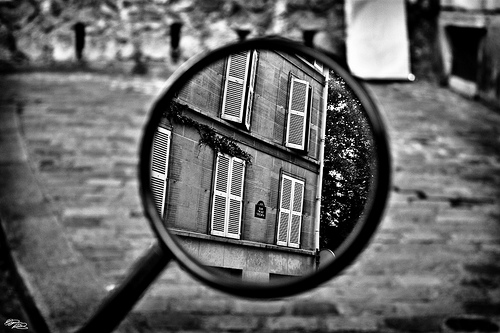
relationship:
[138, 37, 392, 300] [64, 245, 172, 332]
rear view mirror has arm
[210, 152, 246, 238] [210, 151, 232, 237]
window has shutter